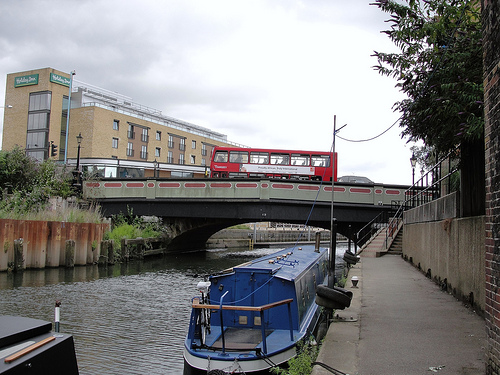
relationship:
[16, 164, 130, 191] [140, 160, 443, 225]
bush next to bridge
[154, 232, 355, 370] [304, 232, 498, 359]
canal between street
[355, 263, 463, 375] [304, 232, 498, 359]
sidewalk has nobody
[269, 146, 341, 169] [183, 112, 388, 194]
window on bus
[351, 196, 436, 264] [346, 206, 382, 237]
stair with railing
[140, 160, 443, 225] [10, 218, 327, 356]
bridge over river